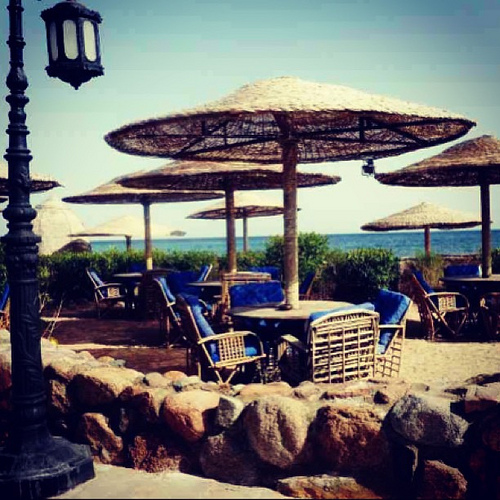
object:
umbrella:
[102, 75, 476, 312]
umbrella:
[373, 133, 499, 278]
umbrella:
[114, 160, 342, 273]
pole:
[279, 144, 300, 310]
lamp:
[39, 2, 104, 90]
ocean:
[90, 228, 500, 260]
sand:
[404, 339, 489, 381]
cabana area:
[0, 254, 499, 498]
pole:
[0, 4, 95, 500]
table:
[230, 300, 352, 319]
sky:
[0, 0, 499, 242]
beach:
[42, 302, 500, 411]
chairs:
[177, 293, 267, 383]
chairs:
[278, 302, 381, 384]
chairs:
[372, 288, 414, 377]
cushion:
[183, 294, 256, 362]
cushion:
[306, 302, 375, 334]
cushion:
[372, 289, 410, 355]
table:
[439, 277, 500, 310]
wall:
[70, 374, 500, 499]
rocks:
[0, 320, 499, 499]